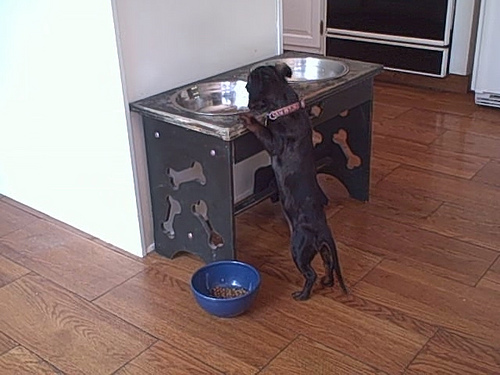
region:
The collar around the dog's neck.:
[266, 102, 305, 119]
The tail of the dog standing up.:
[323, 234, 353, 299]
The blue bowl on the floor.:
[186, 253, 268, 320]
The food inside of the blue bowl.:
[207, 284, 248, 303]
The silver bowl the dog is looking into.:
[169, 82, 258, 117]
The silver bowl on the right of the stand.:
[254, 55, 349, 80]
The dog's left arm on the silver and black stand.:
[234, 110, 280, 156]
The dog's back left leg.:
[287, 241, 319, 304]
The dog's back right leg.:
[318, 245, 337, 285]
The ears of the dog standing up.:
[234, 60, 296, 90]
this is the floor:
[25, 252, 118, 371]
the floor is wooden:
[14, 263, 132, 352]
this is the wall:
[12, 29, 94, 160]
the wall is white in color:
[13, 27, 91, 207]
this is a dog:
[245, 66, 348, 294]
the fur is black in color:
[281, 122, 315, 204]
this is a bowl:
[188, 265, 263, 310]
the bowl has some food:
[204, 276, 240, 295]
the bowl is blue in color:
[202, 268, 243, 283]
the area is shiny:
[291, 64, 337, 74]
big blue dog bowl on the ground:
[190, 260, 260, 315]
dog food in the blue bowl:
[212, 283, 239, 298]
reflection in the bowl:
[227, 276, 244, 288]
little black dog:
[242, 62, 351, 301]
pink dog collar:
[265, 100, 298, 117]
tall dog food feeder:
[130, 37, 383, 262]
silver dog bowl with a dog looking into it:
[173, 61, 299, 121]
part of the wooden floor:
[32, 265, 172, 360]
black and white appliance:
[326, 1, 456, 76]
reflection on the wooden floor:
[422, 100, 498, 212]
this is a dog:
[243, 65, 365, 297]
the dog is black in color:
[279, 160, 299, 200]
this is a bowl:
[196, 263, 275, 328]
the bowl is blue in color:
[213, 296, 240, 309]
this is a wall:
[16, 26, 117, 195]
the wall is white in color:
[48, 52, 110, 142]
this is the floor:
[367, 207, 482, 333]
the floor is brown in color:
[389, 200, 458, 285]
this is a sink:
[189, 70, 236, 119]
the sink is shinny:
[209, 85, 224, 105]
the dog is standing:
[251, 65, 328, 283]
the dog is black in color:
[290, 165, 313, 195]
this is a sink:
[196, 87, 228, 108]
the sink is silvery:
[192, 76, 232, 108]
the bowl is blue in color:
[218, 268, 238, 280]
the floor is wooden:
[387, 258, 470, 373]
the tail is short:
[327, 252, 349, 284]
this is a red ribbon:
[270, 92, 302, 121]